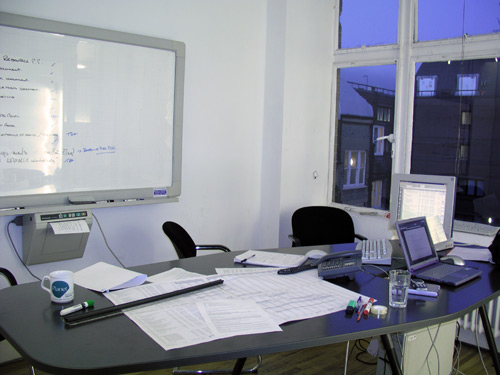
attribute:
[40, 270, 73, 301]
mug — white, blue, coffee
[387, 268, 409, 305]
glass — clear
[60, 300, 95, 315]
marker — green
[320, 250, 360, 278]
telephone — black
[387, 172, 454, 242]
monitor — grey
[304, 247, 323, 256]
mouse — grey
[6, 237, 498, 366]
desk — black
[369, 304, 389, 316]
tape — clear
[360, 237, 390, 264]
keyboard — grey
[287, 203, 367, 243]
chair — black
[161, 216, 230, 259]
chair — black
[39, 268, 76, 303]
cup — white, blue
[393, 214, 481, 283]
laptop — open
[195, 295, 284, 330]
paper — white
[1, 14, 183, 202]
erase board — white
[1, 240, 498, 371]
table — dark gray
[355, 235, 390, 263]
keyboard — gray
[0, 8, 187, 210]
board — white